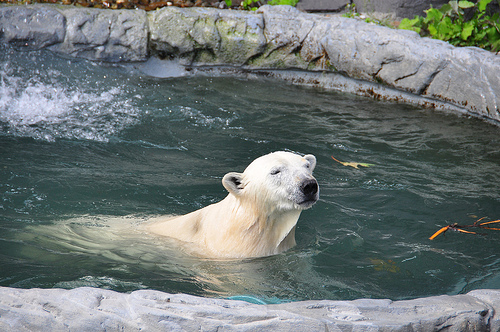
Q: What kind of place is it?
A: It is a swimming pool.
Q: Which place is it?
A: It is a swimming pool.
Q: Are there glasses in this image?
A: No, there are no glasses.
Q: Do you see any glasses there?
A: No, there are no glasses.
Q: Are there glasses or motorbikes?
A: No, there are no glasses or motorbikes.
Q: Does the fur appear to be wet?
A: Yes, the fur is wet.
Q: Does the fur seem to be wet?
A: Yes, the fur is wet.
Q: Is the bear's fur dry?
A: No, the fur is wet.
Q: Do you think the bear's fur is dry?
A: No, the fur is wet.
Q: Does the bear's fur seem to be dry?
A: No, the fur is wet.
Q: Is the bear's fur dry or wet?
A: The fur is wet.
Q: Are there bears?
A: Yes, there is a bear.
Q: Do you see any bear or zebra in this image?
A: Yes, there is a bear.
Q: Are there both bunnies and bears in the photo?
A: No, there is a bear but no bunnies.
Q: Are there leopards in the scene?
A: No, there are no leopards.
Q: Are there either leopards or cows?
A: No, there are no leopards or cows.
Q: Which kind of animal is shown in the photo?
A: The animal is a bear.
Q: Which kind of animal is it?
A: The animal is a bear.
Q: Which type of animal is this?
A: This is a bear.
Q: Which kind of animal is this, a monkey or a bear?
A: This is a bear.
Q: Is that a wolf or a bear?
A: That is a bear.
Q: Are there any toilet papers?
A: No, there are no toilet papers.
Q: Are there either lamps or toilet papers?
A: No, there are no toilet papers or lamps.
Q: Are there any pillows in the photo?
A: No, there are no pillows.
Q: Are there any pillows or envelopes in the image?
A: No, there are no pillows or envelopes.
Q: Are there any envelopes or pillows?
A: No, there are no pillows or envelopes.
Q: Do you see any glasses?
A: No, there are no glasses.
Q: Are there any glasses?
A: No, there are no glasses.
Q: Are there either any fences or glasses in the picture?
A: No, there are no glasses or fences.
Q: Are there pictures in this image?
A: No, there are no pictures.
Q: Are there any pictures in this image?
A: No, there are no pictures.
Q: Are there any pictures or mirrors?
A: No, there are no pictures or mirrors.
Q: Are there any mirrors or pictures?
A: No, there are no pictures or mirrors.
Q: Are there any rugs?
A: No, there are no rugs.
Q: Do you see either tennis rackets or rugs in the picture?
A: No, there are no rugs or tennis rackets.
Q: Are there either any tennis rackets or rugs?
A: No, there are no rugs or tennis rackets.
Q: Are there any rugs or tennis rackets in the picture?
A: No, there are no rugs or tennis rackets.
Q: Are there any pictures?
A: No, there are no pictures.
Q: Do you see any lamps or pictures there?
A: No, there are no pictures or lamps.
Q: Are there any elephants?
A: No, there are no elephants.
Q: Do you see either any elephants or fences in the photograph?
A: No, there are no elephants or fences.